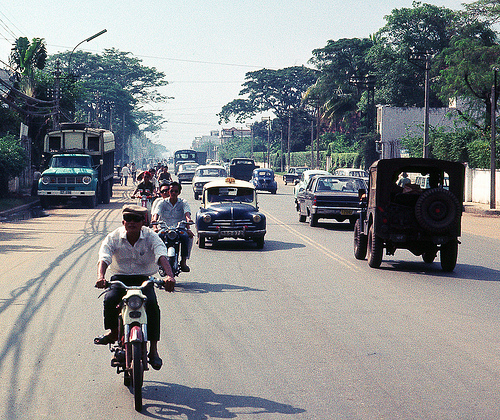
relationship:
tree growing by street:
[12, 37, 40, 169] [266, 222, 305, 404]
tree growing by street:
[59, 50, 160, 124] [266, 222, 305, 404]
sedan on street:
[292, 135, 369, 248] [263, 229, 348, 405]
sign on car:
[220, 174, 240, 191] [186, 173, 278, 250]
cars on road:
[196, 177, 272, 251] [246, 229, 493, 394]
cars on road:
[201, 150, 278, 193] [246, 229, 493, 394]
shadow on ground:
[139, 380, 306, 418] [3, 169, 499, 419]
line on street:
[257, 204, 367, 278] [2, 147, 495, 418]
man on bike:
[95, 203, 175, 370] [97, 275, 169, 408]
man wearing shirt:
[95, 203, 175, 370] [152, 199, 187, 234]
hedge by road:
[250, 141, 372, 184] [224, 158, 494, 291]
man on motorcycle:
[87, 196, 177, 375] [80, 230, 185, 402]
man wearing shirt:
[87, 196, 177, 375] [90, 215, 174, 282]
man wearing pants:
[95, 203, 175, 370] [101, 271, 160, 343]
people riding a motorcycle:
[151, 180, 195, 272] [152, 217, 195, 283]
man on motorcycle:
[95, 203, 175, 370] [79, 255, 178, 395]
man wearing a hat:
[95, 203, 175, 370] [111, 187, 153, 226]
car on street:
[106, 126, 283, 247] [2, 147, 495, 418]